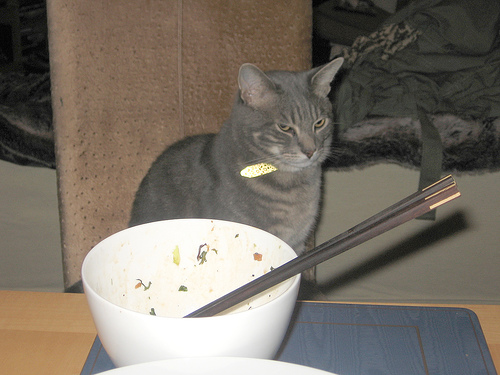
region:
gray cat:
[181, 20, 413, 211]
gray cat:
[272, 58, 367, 155]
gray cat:
[183, 30, 314, 245]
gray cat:
[214, 77, 355, 237]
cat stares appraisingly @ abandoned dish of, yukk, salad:
[116, 40, 363, 303]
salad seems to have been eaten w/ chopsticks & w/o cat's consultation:
[163, 173, 466, 339]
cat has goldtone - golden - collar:
[233, 160, 279, 182]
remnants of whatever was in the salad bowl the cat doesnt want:
[101, 230, 286, 329]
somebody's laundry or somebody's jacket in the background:
[330, 0, 499, 217]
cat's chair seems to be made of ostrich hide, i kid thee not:
[52, 0, 316, 292]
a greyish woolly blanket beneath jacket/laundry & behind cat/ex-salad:
[2, 0, 499, 182]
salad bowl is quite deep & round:
[75, 206, 307, 373]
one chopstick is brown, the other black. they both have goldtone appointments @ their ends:
[174, 168, 466, 329]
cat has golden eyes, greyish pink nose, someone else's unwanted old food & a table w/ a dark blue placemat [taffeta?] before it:
[267, 112, 331, 167]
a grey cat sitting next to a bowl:
[123, 42, 350, 275]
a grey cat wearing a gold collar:
[211, 52, 353, 202]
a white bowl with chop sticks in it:
[58, 185, 363, 369]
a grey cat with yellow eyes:
[238, 56, 365, 165]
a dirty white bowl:
[55, 235, 310, 363]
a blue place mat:
[264, 291, 489, 373]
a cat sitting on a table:
[107, 48, 407, 371]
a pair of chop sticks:
[108, 170, 475, 347]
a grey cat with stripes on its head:
[229, 55, 346, 172]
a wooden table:
[33, 286, 98, 373]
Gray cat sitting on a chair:
[48, 2, 351, 296]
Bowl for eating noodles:
[78, 207, 309, 367]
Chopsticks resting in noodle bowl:
[76, 175, 461, 372]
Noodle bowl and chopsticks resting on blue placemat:
[71, 173, 497, 373]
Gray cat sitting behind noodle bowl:
[78, 33, 457, 373]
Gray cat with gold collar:
[135, 53, 350, 222]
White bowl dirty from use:
[74, 214, 310, 373]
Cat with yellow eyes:
[132, 48, 349, 226]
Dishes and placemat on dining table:
[3, 216, 498, 374]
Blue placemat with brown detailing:
[77, 298, 491, 369]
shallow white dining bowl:
[79, 223, 299, 373]